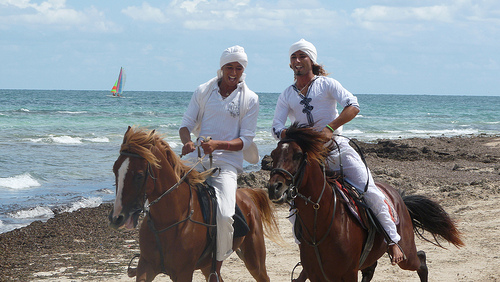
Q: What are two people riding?
A: Horses.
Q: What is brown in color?
A: The horses.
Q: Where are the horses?
A: On the beach.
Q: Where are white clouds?
A: In the sky.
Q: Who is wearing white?
A: Two people on horses.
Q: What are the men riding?
A: Horses.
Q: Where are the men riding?
A: On a beach.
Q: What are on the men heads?
A: Turbans.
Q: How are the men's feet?
A: Bare.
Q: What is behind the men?
A: Water.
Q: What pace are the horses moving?
A: Galloping.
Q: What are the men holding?
A: Reins.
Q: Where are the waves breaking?
A: Close to the shore.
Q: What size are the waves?
A: Very small.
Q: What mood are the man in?
A: Happy mood.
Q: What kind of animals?
A: Horses.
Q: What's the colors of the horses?
A: Brown and white.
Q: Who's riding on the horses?
A: Two men.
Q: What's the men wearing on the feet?
A: Nothing.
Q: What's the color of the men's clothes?
A: White.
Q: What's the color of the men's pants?
A: White.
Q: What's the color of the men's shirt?
A: White.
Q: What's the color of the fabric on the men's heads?
A: White.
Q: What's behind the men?
A: Water.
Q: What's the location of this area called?
A: Beach.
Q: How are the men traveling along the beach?
A: Riding horses.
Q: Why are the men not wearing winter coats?
A: Warm weather.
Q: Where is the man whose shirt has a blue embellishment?
A: Right.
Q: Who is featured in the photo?
A: Two men.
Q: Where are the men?
A: On the beach.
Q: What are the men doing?
A: Riding horses.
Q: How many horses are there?
A: Two.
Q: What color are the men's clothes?
A: White.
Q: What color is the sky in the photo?
A: Blue.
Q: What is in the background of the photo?
A: A boat.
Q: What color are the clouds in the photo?
A: White.